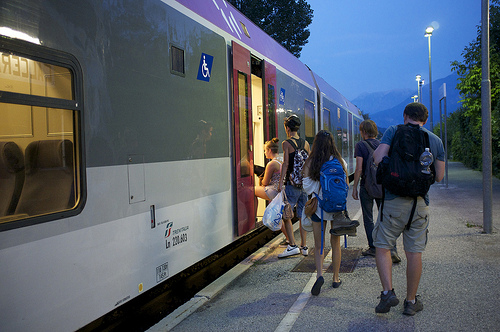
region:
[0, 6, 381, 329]
a green and white train car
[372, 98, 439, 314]
a man with a backpack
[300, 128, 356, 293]
a girl with a backpack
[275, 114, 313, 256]
a man with a bag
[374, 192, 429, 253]
a pair of men's khaki short pants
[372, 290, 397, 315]
a grey athletic shoe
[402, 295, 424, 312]
a grey athletic shoe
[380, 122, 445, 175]
a men's blue t-shirt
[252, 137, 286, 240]
a woman boarding a train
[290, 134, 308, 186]
a black and white backpack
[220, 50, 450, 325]
Passengers boarding a train at night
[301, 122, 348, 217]
Girl carrying a blue backpack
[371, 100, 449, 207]
Man carrying a black backpack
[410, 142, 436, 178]
Water bottle inside a backpack pocket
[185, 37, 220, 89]
Disabled persons boarding sign notice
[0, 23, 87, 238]
Window of a passenger train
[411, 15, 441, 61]
Light over a train station boarding area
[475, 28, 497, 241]
Metal pole on a sidewalk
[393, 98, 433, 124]
Person dark colored brown hair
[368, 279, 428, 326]
Shoes on a person's feet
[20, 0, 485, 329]
People getting on a train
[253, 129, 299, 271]
A girl stepping into a train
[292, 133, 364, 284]
A girl with a bright blue backpack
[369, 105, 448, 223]
A boy with a black backpack with red writing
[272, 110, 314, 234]
A boy in a baseball cap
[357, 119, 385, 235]
A boy in a blue tshirt and blue jeans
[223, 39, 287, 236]
Red train doors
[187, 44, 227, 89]
A blue and white handicap sign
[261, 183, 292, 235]
A white plastic bag with blue writing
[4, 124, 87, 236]
A train seat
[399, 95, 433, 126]
the head of a man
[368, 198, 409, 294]
the leg of a man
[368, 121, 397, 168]
the arm of a man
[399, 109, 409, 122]
the ear of a man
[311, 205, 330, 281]
the leg of a woman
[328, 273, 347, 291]
a black shoe on the woman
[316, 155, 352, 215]
a blue backpack on the woman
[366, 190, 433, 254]
a gray pair of shorts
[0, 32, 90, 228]
a window on the train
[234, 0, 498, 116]
a blue sky overhead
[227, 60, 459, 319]
people about to board a train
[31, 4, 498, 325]
a train stopped at a rain station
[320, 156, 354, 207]
a blue backpack on woman's shoulders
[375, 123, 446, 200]
a black backpack on man's shoulders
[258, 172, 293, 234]
woman carrying a plastic bag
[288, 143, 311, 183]
a white and blue backpack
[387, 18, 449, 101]
a row of illuminated streetlamps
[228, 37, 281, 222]
an open red door of a train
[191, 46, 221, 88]
a blue and white handicap sign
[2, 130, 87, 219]
comfortable seats on a train